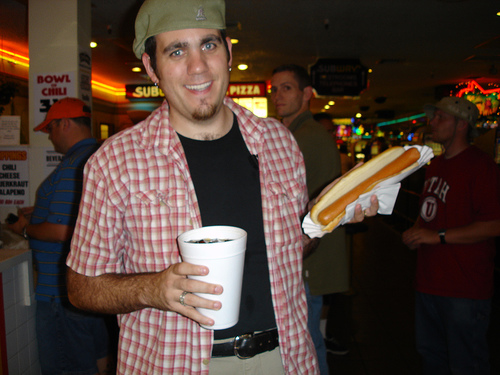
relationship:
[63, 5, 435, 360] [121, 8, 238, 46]
man wearing hat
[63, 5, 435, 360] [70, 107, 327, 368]
man wearing shirt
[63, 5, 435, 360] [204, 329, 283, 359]
man wearing belt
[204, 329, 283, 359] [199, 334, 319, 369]
belt holding pants